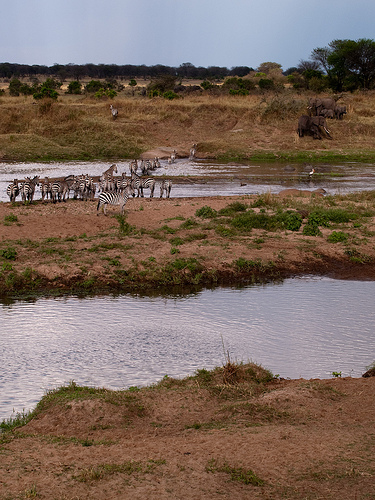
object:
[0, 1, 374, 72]
sky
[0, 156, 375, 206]
river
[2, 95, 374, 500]
grass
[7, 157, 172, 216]
stripes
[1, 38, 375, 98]
trees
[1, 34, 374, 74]
horizon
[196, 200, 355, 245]
shrubs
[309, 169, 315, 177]
bird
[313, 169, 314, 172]
beak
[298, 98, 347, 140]
elephant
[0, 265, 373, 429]
water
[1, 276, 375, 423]
ripples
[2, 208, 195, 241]
dirt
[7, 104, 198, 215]
zebra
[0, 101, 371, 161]
hill